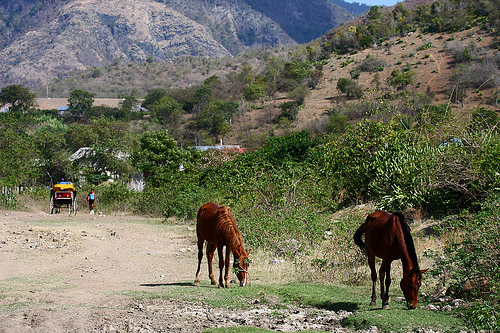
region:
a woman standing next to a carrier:
[84, 193, 104, 222]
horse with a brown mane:
[187, 203, 263, 295]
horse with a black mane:
[368, 210, 442, 314]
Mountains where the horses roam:
[114, 7, 332, 64]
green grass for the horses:
[304, 282, 348, 307]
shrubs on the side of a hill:
[324, 73, 380, 106]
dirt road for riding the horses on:
[36, 225, 126, 317]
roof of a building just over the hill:
[20, 91, 129, 117]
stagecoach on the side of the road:
[45, 176, 78, 218]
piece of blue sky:
[361, 1, 404, 12]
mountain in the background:
[2, 0, 368, 95]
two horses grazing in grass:
[190, 195, 442, 315]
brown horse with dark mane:
[344, 199, 430, 314]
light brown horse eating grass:
[173, 197, 260, 290]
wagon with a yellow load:
[41, 167, 88, 227]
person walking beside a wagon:
[83, 182, 104, 219]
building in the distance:
[0, 84, 154, 128]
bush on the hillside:
[347, 51, 391, 74]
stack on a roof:
[210, 129, 229, 153]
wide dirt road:
[0, 207, 165, 327]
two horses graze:
[195, 200, 420, 309]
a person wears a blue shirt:
[91, 190, 96, 197]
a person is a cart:
[49, 184, 76, 209]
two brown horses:
[198, 200, 425, 314]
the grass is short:
[167, 273, 479, 328]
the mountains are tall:
[4, 0, 494, 109]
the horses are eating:
[197, 205, 425, 309]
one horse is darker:
[360, 209, 423, 311]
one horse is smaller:
[193, 205, 248, 288]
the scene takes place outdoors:
[2, 0, 496, 330]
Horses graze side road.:
[189, 193, 432, 311]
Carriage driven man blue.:
[42, 174, 84, 222]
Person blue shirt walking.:
[82, 179, 108, 217]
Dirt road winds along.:
[60, 210, 160, 322]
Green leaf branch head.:
[224, 255, 256, 284]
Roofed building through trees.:
[3, 91, 158, 131]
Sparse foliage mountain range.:
[20, 0, 315, 94]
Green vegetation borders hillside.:
[148, 139, 438, 221]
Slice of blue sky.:
[330, 0, 410, 16]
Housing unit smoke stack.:
[189, 133, 253, 157]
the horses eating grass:
[153, 143, 440, 317]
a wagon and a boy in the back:
[20, 167, 133, 226]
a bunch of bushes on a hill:
[149, 66, 469, 206]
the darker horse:
[336, 197, 455, 324]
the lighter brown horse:
[166, 186, 276, 282]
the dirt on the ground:
[24, 227, 176, 322]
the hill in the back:
[55, 18, 186, 60]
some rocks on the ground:
[156, 301, 271, 320]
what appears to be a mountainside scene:
[13, 67, 443, 157]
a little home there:
[182, 132, 259, 164]